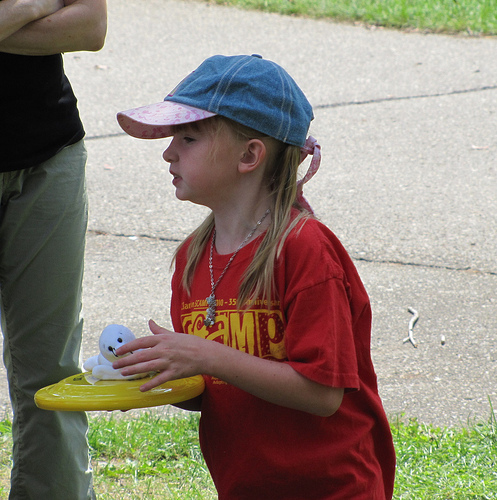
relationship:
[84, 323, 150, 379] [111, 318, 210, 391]
stuffed toy in hand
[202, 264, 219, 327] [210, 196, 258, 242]
necklace around girl's neck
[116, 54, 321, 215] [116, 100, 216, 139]
cap with rim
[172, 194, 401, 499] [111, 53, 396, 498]
red shirt on girl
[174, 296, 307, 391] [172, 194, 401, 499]
letters on red shirt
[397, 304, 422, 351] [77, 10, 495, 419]
twig on road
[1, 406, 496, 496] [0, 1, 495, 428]
grass beside road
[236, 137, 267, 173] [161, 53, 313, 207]
ear on head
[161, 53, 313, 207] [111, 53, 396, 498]
head on girl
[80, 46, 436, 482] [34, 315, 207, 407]
girl holding toys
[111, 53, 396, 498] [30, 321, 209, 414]
girl holding toy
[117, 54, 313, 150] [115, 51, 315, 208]
cap on head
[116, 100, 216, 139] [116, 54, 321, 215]
rim on cap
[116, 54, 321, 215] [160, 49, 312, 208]
cap on head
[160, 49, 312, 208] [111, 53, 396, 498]
head on girl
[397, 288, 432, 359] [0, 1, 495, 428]
twig on road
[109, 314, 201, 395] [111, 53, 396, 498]
hands on girl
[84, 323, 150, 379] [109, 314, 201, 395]
stuffed toy in hands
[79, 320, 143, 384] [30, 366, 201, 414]
stuffed toy on frisbee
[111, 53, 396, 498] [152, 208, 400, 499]
girl wearing red shirt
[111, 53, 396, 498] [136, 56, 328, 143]
girl wearing hat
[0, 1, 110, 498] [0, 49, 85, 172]
adult wearing shirt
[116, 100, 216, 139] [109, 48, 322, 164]
rim with cap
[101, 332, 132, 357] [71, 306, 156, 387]
face on toy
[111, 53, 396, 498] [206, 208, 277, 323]
girl wearing necklace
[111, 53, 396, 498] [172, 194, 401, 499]
girl wearing red shirt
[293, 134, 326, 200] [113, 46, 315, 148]
strap on cap